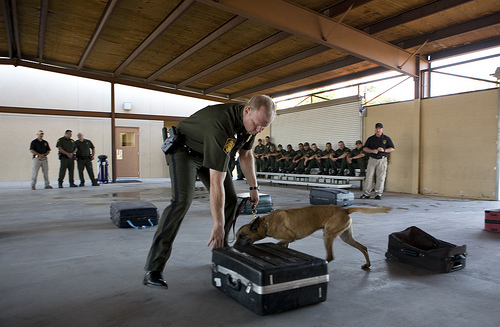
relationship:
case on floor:
[207, 240, 331, 312] [4, 170, 484, 324]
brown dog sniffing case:
[236, 203, 373, 269] [207, 240, 331, 312]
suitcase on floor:
[384, 224, 469, 274] [4, 170, 484, 324]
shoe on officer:
[141, 265, 169, 287] [144, 95, 276, 289]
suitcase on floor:
[479, 204, 498, 234] [118, 170, 483, 320]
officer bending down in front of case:
[144, 95, 276, 289] [207, 240, 331, 312]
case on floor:
[207, 240, 331, 312] [3, 182, 499, 326]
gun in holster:
[164, 124, 176, 137] [161, 139, 177, 150]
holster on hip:
[161, 139, 177, 150] [160, 124, 199, 162]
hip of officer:
[160, 124, 199, 162] [144, 95, 276, 289]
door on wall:
[112, 125, 139, 181] [1, 62, 219, 187]